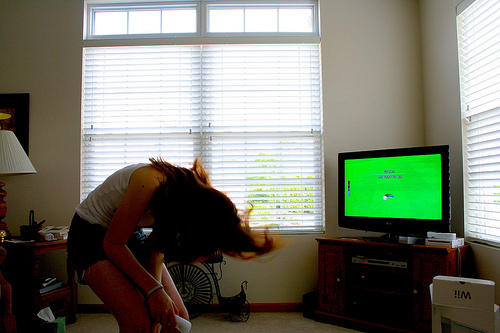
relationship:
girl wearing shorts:
[65, 157, 287, 332] [60, 208, 148, 271]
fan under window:
[168, 265, 220, 316] [83, 0, 320, 237]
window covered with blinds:
[83, 0, 320, 237] [75, 39, 327, 239]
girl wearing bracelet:
[67, 164, 282, 310] [130, 236, 183, 308]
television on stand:
[337, 144, 450, 245] [303, 237, 467, 332]